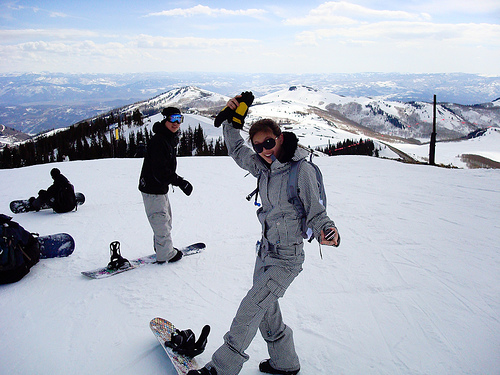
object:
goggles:
[164, 114, 185, 124]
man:
[137, 106, 192, 263]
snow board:
[81, 239, 207, 280]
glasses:
[253, 135, 281, 153]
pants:
[140, 190, 177, 262]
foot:
[184, 362, 243, 375]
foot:
[257, 358, 303, 372]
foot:
[157, 247, 184, 264]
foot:
[24, 202, 34, 212]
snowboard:
[33, 232, 78, 260]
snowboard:
[6, 193, 88, 213]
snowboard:
[146, 315, 244, 374]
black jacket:
[138, 119, 181, 196]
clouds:
[1, 42, 32, 52]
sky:
[0, 0, 499, 75]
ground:
[452, 348, 496, 371]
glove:
[212, 89, 252, 128]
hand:
[227, 94, 242, 111]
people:
[176, 89, 339, 375]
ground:
[411, 179, 460, 202]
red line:
[333, 149, 340, 151]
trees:
[374, 148, 380, 157]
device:
[324, 229, 336, 241]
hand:
[318, 223, 342, 247]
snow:
[350, 179, 374, 190]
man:
[29, 167, 81, 214]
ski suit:
[206, 124, 339, 375]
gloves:
[226, 95, 254, 128]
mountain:
[0, 144, 497, 374]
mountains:
[269, 83, 349, 102]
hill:
[76, 81, 187, 126]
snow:
[378, 354, 399, 372]